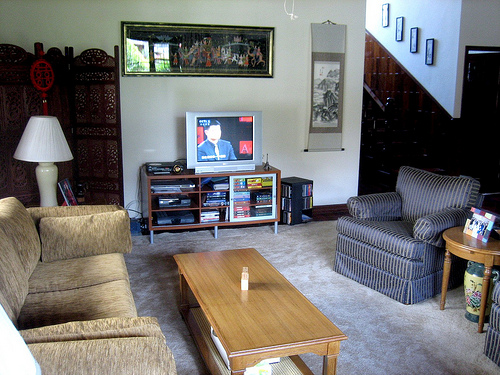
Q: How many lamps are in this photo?
A: One.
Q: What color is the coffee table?
A: Brown.